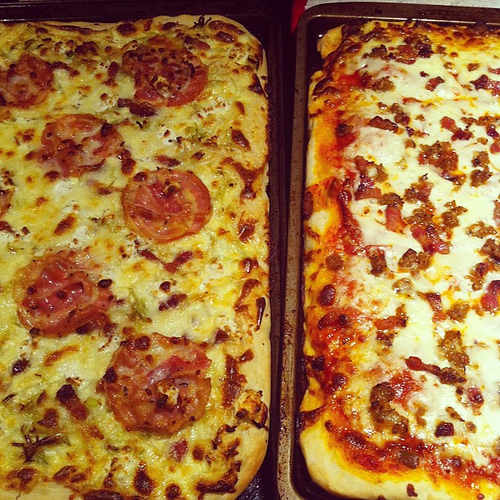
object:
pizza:
[0, 14, 271, 499]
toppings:
[11, 241, 111, 336]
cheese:
[132, 122, 182, 162]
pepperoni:
[39, 114, 128, 179]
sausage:
[444, 200, 468, 229]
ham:
[412, 224, 449, 253]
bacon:
[354, 182, 384, 201]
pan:
[273, 4, 499, 499]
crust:
[228, 17, 272, 499]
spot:
[231, 127, 252, 152]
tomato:
[331, 133, 356, 149]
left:
[0, 0, 282, 499]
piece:
[117, 168, 213, 243]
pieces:
[5, 34, 216, 436]